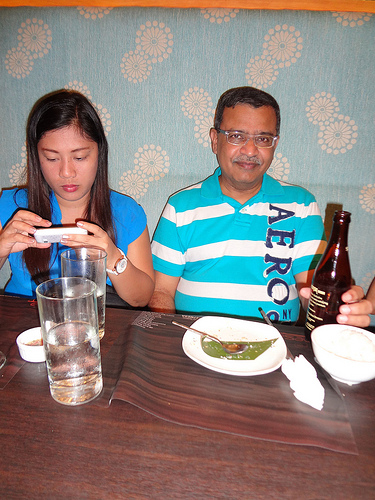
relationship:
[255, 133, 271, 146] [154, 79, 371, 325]
eye of seated man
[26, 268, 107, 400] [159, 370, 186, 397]
water sitting on a table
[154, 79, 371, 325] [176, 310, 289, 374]
man seated for dinner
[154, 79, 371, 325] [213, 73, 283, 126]
man on hair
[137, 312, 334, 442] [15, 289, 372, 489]
cloth on table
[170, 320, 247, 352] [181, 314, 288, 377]
spoon on plate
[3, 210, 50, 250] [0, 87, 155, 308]
hand of girl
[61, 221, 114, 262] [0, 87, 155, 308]
hand seated girl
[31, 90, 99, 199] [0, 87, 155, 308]
head of girl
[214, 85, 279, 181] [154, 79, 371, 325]
head of man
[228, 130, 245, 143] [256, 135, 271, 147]
eye of eye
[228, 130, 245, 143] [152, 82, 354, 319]
eye of man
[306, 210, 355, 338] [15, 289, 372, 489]
glass bottle on a table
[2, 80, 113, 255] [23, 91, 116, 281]
girl with hair